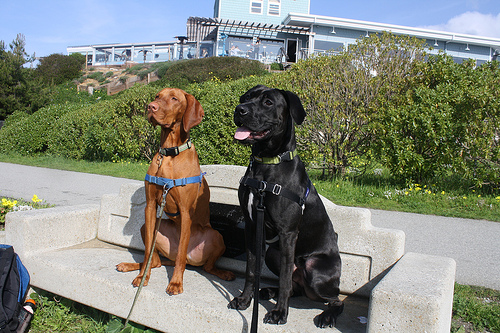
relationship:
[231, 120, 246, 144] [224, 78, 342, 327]
tongue on dog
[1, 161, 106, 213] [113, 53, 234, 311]
sidewalk behind dog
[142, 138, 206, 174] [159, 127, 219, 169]
collar around neck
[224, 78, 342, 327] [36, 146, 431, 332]
dog on bench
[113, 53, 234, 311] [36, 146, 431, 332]
dog on bench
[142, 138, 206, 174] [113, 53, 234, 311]
collar on dog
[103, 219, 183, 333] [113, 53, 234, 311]
leash on dog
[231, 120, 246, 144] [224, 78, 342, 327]
tongue of dog